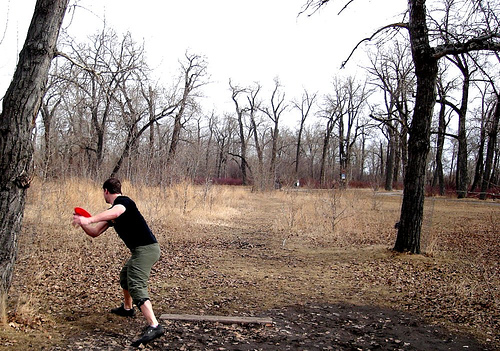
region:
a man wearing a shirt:
[35, 125, 242, 338]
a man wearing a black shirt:
[57, 157, 221, 347]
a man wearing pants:
[44, 132, 236, 341]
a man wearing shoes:
[47, 160, 222, 347]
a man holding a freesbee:
[59, 149, 215, 330]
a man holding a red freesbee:
[35, 150, 240, 347]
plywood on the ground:
[155, 277, 276, 349]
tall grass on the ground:
[144, 149, 382, 268]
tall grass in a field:
[161, 154, 347, 305]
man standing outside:
[72, 141, 285, 346]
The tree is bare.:
[363, 2, 499, 275]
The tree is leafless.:
[338, 1, 499, 264]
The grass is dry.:
[3, 173, 498, 348]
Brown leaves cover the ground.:
[7, 177, 499, 349]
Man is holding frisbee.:
[60, 168, 180, 347]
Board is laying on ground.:
[152, 295, 284, 340]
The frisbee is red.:
[61, 190, 104, 245]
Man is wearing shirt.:
[63, 162, 185, 349]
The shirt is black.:
[85, 170, 164, 265]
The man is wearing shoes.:
[64, 164, 180, 349]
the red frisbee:
[69, 205, 96, 224]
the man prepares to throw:
[69, 169, 162, 348]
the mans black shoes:
[105, 302, 167, 342]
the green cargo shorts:
[112, 242, 159, 302]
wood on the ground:
[154, 308, 275, 326]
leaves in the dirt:
[304, 302, 371, 349]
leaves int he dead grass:
[227, 225, 302, 297]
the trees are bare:
[87, 71, 373, 144]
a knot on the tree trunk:
[12, 165, 33, 193]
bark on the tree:
[403, 182, 422, 249]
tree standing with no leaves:
[225, 97, 255, 182]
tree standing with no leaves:
[253, 117, 276, 189]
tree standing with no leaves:
[292, 97, 306, 189]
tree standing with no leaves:
[314, 99, 328, 181]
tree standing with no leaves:
[386, 37, 438, 257]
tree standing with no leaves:
[153, 42, 190, 182]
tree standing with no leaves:
[73, 45, 107, 176]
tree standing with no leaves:
[169, 67, 196, 208]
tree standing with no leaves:
[131, 80, 166, 166]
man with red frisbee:
[69, 173, 171, 339]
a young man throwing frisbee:
[70, 180, 167, 350]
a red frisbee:
[72, 202, 91, 221]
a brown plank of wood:
[152, 306, 272, 326]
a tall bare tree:
[375, 0, 495, 261]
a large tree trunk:
[0, 0, 68, 285]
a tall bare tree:
[216, 79, 249, 174]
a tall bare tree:
[242, 79, 267, 179]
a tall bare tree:
[265, 72, 285, 174]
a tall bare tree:
[289, 84, 311, 181]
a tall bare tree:
[329, 75, 366, 177]